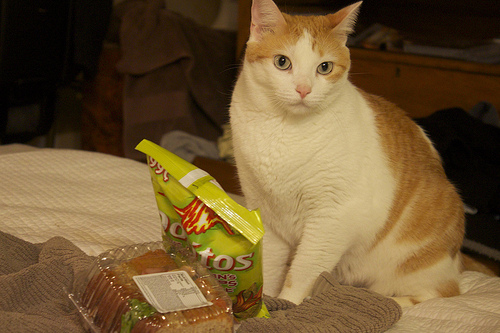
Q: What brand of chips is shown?
A: Doritos.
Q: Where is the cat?
A: By the food.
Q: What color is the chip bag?
A: Green.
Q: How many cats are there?
A: One.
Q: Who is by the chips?
A: The cat.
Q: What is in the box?
A: Strawberries.